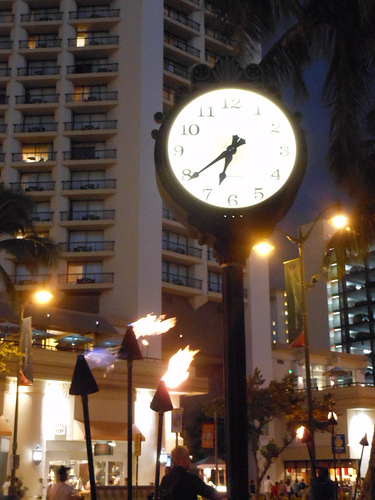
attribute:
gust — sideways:
[124, 314, 180, 350]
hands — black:
[186, 132, 246, 189]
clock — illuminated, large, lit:
[149, 59, 311, 238]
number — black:
[181, 120, 202, 137]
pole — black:
[210, 239, 257, 499]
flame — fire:
[128, 313, 177, 338]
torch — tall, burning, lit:
[116, 326, 147, 500]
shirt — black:
[156, 468, 221, 500]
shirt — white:
[42, 480, 83, 500]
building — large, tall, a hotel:
[1, 3, 286, 488]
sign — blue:
[327, 434, 349, 455]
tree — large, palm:
[1, 179, 64, 500]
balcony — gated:
[64, 85, 121, 109]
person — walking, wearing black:
[153, 447, 226, 500]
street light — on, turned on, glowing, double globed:
[318, 196, 363, 355]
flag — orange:
[276, 252, 310, 351]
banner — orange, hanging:
[198, 424, 217, 449]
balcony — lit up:
[8, 149, 63, 169]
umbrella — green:
[57, 329, 98, 353]